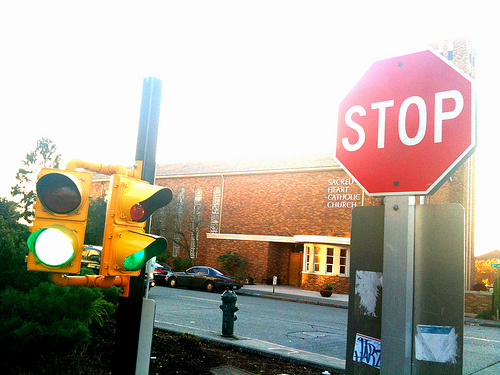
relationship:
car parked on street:
[162, 262, 244, 294] [151, 279, 499, 373]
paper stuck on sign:
[414, 322, 461, 364] [343, 200, 466, 372]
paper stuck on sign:
[354, 265, 382, 313] [343, 200, 466, 372]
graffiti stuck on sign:
[350, 332, 384, 369] [343, 200, 466, 372]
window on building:
[205, 185, 223, 237] [153, 166, 473, 310]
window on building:
[189, 183, 203, 261] [153, 166, 473, 310]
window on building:
[167, 182, 184, 269] [153, 166, 473, 310]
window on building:
[152, 202, 165, 240] [153, 166, 473, 310]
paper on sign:
[414, 322, 461, 364] [343, 200, 466, 372]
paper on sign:
[354, 265, 382, 317] [343, 200, 466, 372]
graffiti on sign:
[350, 332, 384, 369] [343, 200, 466, 372]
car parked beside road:
[162, 260, 243, 294] [153, 279, 496, 373]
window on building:
[184, 183, 203, 269] [152, 150, 472, 294]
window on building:
[172, 182, 184, 260] [152, 150, 472, 294]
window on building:
[158, 202, 165, 241] [152, 150, 472, 294]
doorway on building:
[283, 245, 304, 288] [153, 166, 473, 310]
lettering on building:
[324, 174, 361, 211] [85, 38, 493, 314]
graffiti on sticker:
[350, 332, 385, 364] [349, 330, 381, 366]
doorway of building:
[286, 247, 304, 288] [85, 38, 493, 314]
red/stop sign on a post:
[333, 42, 480, 198] [378, 195, 415, 373]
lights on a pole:
[23, 158, 174, 297] [133, 72, 165, 182]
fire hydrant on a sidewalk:
[217, 283, 242, 339] [159, 315, 303, 355]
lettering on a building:
[322, 174, 352, 211] [154, 158, 479, 316]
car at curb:
[162, 262, 244, 294] [240, 284, 297, 304]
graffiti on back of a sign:
[350, 332, 384, 369] [343, 200, 466, 372]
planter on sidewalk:
[317, 281, 335, 298] [274, 285, 318, 297]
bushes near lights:
[1, 284, 118, 371] [23, 158, 174, 297]